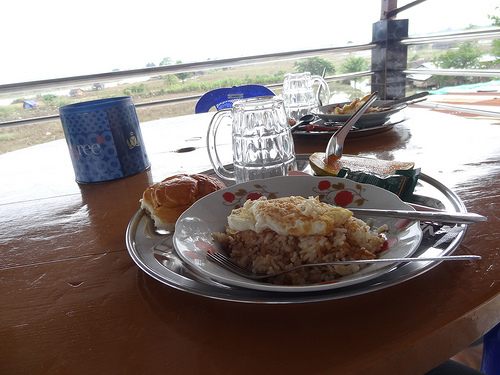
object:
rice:
[286, 249, 300, 265]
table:
[0, 91, 499, 374]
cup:
[204, 96, 298, 184]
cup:
[279, 70, 329, 126]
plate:
[168, 177, 423, 292]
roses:
[221, 190, 236, 204]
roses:
[333, 189, 356, 207]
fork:
[203, 250, 482, 281]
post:
[368, 19, 409, 102]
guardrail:
[0, 27, 497, 134]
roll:
[140, 173, 227, 234]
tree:
[433, 39, 486, 72]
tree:
[337, 54, 366, 87]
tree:
[293, 55, 335, 84]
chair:
[191, 84, 274, 113]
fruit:
[304, 152, 416, 188]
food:
[224, 192, 353, 239]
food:
[328, 98, 384, 115]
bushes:
[121, 71, 286, 100]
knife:
[326, 203, 489, 225]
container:
[57, 96, 152, 184]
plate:
[306, 99, 408, 130]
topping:
[227, 193, 352, 235]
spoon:
[324, 90, 380, 160]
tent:
[20, 99, 36, 111]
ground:
[0, 48, 353, 152]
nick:
[65, 282, 86, 289]